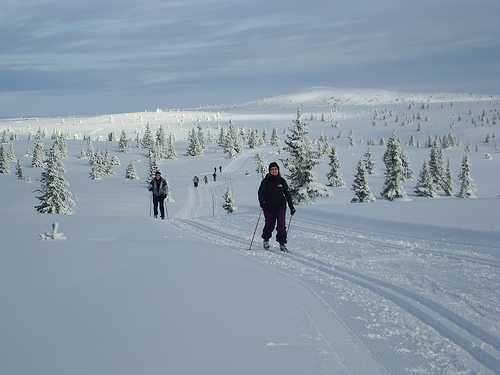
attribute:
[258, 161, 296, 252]
woman — skiing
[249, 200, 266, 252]
ski pole — red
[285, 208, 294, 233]
ski pole — red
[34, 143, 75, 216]
tree — pine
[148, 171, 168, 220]
man — skiing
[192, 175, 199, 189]
person — skiing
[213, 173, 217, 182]
person — skiing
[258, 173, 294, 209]
jacket — black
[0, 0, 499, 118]
sky — cloudy, grey, dark, blue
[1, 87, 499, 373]
snow — white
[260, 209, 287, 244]
pants — purple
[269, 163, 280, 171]
hat — black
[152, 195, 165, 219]
pants — black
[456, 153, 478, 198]
tree — pine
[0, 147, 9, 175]
tree — pine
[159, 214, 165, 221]
boot — dark